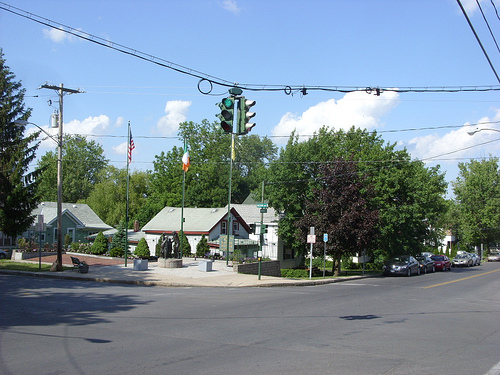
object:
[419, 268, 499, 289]
line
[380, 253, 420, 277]
parked cars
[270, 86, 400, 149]
cloud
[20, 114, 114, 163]
cloud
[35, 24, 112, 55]
cloud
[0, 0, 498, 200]
sky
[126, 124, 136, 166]
flags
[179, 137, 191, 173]
flags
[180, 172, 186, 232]
poles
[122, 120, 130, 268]
poles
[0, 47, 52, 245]
tree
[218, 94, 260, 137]
streetlight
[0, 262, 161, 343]
shadow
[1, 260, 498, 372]
street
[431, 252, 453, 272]
red car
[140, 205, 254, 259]
white house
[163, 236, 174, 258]
statue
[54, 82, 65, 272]
pole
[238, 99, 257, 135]
bright light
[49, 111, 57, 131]
transformer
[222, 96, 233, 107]
light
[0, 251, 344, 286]
courtyard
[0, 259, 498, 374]
road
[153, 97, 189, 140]
cloud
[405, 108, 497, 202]
cloud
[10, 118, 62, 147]
light